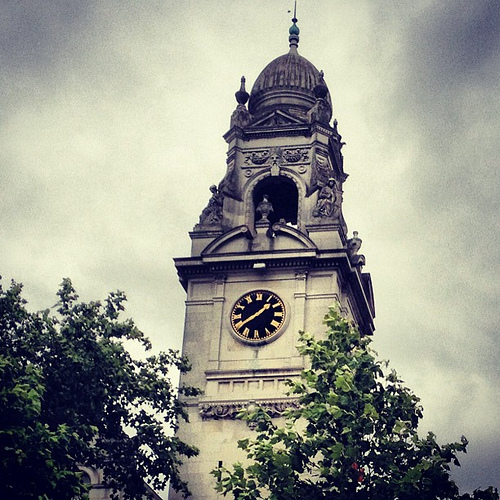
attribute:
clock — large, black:
[229, 289, 289, 346]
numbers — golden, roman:
[232, 295, 281, 342]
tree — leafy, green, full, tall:
[211, 299, 499, 500]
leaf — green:
[333, 376, 345, 390]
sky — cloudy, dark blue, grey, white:
[2, 1, 500, 499]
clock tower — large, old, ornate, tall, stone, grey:
[168, 1, 376, 499]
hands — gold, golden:
[236, 301, 270, 327]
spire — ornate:
[289, 2, 300, 54]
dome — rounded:
[250, 51, 332, 102]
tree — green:
[1, 275, 206, 500]